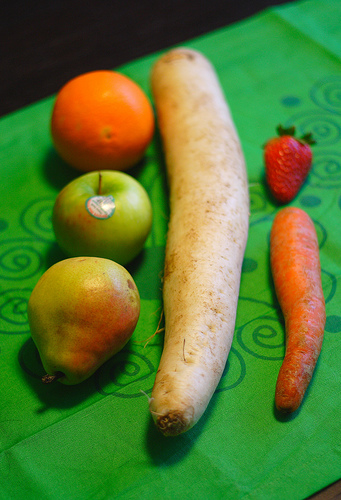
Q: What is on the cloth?
A: The carrot.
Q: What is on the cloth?
A: The pair.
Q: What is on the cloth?
A: The orange.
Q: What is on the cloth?
A: The fruits and vegetables.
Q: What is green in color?
A: The cloth.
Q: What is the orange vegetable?
A: A carrot.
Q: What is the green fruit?
A: An apple.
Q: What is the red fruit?
A: A strawberry.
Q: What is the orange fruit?
A: An orange.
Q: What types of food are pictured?
A: Fruits and vegetables.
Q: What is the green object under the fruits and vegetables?
A: A tablecloth.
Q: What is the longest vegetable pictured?
A: A white root vegetable.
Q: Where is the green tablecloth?
A: Under the fruits and vegetables.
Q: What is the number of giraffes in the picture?
A: Zero.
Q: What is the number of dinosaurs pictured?
A: Zero.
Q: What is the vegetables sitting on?
A: A green tablecloth.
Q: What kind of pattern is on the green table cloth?
A: Swirls.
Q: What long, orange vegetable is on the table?
A: A carrot.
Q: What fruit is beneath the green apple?
A: A pear.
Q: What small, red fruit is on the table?
A: A strawberry.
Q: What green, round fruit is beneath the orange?
A: An apple.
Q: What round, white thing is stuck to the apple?
A: A sticker.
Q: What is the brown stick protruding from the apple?
A: A stem.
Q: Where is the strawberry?
A: Above the carrot.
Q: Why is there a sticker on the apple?
A: To identify it.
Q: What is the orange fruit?
A: An orange.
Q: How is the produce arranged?
A: In 3 lines.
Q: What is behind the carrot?
A: The strawberry.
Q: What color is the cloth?
A: Green.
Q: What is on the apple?
A: A sticker.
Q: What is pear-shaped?
A: The pear.